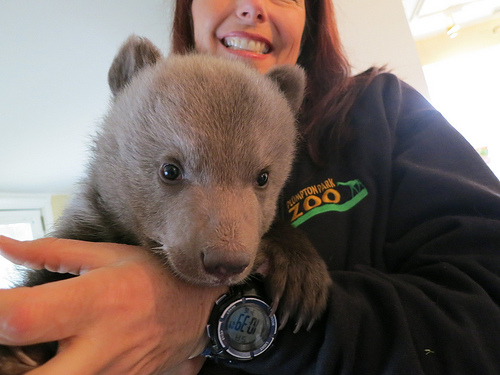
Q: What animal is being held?
A: A bear cub.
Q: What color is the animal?
A: It is brown.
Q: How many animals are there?
A: Just 1.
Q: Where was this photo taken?
A: Zoo.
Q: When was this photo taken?
A: 10:39.